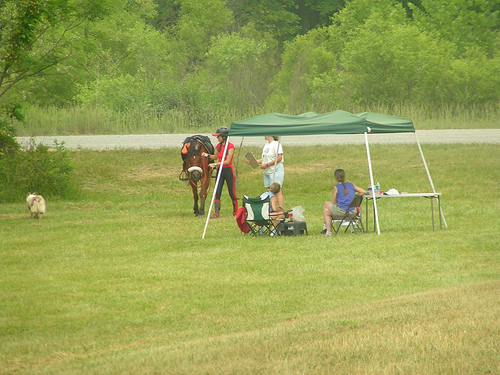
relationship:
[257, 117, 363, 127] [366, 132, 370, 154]
canopy has pole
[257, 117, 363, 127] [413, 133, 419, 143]
canopy has pole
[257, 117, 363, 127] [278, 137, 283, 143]
canopy has pole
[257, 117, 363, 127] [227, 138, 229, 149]
canopy has pole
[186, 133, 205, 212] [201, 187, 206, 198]
horse has leg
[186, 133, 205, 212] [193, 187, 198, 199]
horse has leg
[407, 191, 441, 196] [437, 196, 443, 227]
table has leg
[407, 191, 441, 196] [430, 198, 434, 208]
table has leg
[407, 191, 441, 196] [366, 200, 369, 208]
table has leg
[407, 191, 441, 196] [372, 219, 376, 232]
table has leg